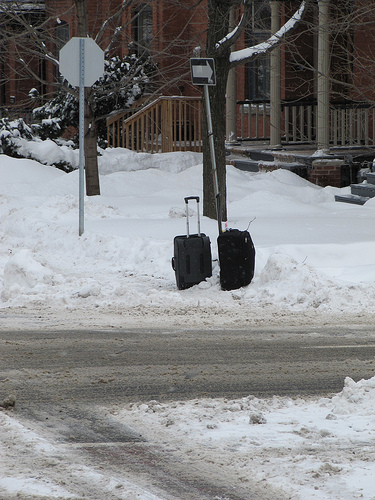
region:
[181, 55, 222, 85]
a street sign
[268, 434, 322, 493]
the snow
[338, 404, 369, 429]
the snow is white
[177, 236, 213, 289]
grey luggage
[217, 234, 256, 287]
black luggage in the snow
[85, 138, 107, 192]
a tree trunk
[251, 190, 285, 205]
a small mountain of snow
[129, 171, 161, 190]
the mountain of snow is white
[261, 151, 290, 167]
the steps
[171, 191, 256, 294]
two black luggages on snow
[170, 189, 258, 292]
two black suitcases sitting on snow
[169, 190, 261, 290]
two black suitcases with long handles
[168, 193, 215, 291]
suitcase sitting on snow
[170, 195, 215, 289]
suitcase with long handle on snow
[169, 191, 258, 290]
black suitcases with long handles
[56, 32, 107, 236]
the back of a stop sign in snow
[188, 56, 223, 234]
arrow sign on a pole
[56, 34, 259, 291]
street signs and luggage in snow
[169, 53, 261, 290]
two suitcases in front of a street sign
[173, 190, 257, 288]
two suitcases in the snow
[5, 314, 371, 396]
road covered in snow sludge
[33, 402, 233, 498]
tire tracks in the snow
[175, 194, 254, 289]
suitcases with their handles pulled up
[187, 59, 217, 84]
black and white street sign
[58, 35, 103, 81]
back of a stop sign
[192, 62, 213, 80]
white arrow on black background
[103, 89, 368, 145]
railings along the building's porch and stairs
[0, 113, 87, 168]
bushes covered in snow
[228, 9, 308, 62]
limbs covered in snow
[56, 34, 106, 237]
back of a stop sign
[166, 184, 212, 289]
gray rolling suitcase in the snow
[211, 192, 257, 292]
black rolling suitcase in the snow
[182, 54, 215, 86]
one way street sign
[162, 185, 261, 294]
two small suitcases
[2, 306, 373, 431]
plowed snowy street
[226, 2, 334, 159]
three white porch columns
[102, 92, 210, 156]
small wooden porch railing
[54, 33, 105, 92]
back of an octagonal street sign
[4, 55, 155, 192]
green bushes covered in snow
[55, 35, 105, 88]
light colored back of octagonal street sign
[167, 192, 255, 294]
two black rectangular suitcases in the snow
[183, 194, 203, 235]
metal telescopic suitcase handle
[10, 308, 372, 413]
slushy snow covered road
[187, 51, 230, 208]
one black and white street sign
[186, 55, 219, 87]
one white arrow on black background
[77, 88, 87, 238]
light gray metal sign pole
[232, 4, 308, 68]
dark thick snow covered tree branch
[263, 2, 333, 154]
two white ridged stone columns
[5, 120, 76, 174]
one dark snow covered bush